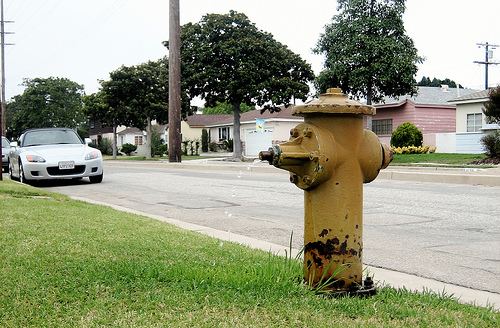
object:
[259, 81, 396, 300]
fire hydrant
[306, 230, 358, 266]
rust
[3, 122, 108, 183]
sports car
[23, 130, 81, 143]
windshield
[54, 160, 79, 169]
license plate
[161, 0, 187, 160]
pole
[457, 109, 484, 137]
window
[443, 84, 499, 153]
house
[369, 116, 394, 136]
window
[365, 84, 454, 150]
house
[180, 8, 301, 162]
tree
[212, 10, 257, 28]
top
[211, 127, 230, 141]
window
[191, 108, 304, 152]
house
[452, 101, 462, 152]
corner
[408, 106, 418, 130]
corner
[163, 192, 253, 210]
asphalt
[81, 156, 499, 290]
street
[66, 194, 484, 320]
curb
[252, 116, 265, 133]
flag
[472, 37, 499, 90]
pole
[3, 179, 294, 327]
grass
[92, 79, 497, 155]
houses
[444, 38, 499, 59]
power lines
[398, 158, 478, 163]
edge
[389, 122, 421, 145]
bush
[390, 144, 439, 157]
flowers